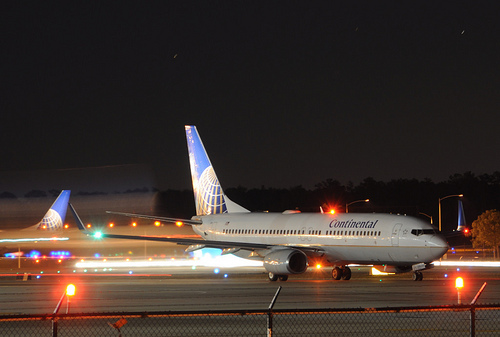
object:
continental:
[329, 219, 379, 229]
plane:
[81, 123, 451, 282]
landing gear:
[412, 270, 423, 281]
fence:
[1, 302, 499, 337]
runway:
[1, 266, 499, 335]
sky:
[1, 1, 499, 190]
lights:
[57, 260, 62, 263]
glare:
[72, 250, 265, 272]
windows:
[222, 229, 225, 234]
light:
[63, 282, 78, 296]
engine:
[263, 247, 309, 276]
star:
[402, 230, 408, 235]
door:
[390, 223, 403, 247]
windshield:
[411, 229, 440, 237]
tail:
[183, 123, 250, 214]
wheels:
[332, 267, 342, 280]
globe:
[196, 164, 228, 215]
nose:
[413, 234, 449, 259]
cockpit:
[402, 220, 437, 238]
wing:
[82, 228, 323, 253]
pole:
[269, 286, 283, 309]